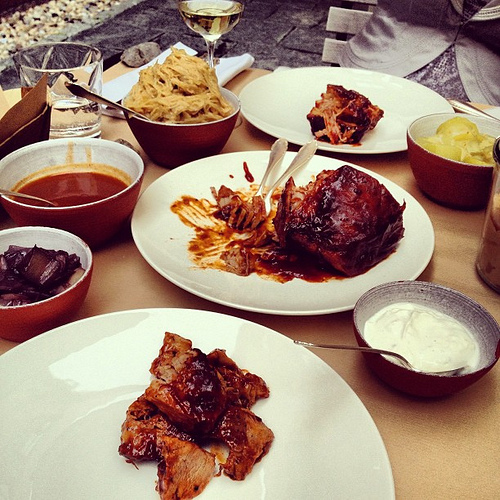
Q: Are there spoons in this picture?
A: Yes, there is a spoon.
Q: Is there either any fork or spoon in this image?
A: Yes, there is a spoon.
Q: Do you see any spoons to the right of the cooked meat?
A: Yes, there is a spoon to the right of the meat.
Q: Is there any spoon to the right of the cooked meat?
A: Yes, there is a spoon to the right of the meat.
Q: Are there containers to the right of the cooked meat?
A: No, there is a spoon to the right of the meat.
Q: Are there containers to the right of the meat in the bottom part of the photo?
A: No, there is a spoon to the right of the meat.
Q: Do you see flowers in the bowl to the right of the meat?
A: No, there is a spoon in the bowl.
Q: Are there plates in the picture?
A: Yes, there is a plate.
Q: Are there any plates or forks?
A: Yes, there is a plate.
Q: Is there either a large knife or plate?
A: Yes, there is a large plate.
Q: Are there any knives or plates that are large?
A: Yes, the plate is large.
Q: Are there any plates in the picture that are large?
A: Yes, there is a large plate.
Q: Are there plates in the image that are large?
A: Yes, there is a plate that is large.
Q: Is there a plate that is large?
A: Yes, there is a plate that is large.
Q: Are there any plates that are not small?
A: Yes, there is a large plate.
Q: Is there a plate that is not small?
A: Yes, there is a large plate.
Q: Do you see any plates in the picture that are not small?
A: Yes, there is a large plate.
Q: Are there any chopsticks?
A: No, there are no chopsticks.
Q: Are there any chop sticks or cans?
A: No, there are no chop sticks or cans.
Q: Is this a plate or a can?
A: This is a plate.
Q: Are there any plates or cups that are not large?
A: No, there is a plate but it is large.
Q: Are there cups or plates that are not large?
A: No, there is a plate but it is large.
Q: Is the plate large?
A: Yes, the plate is large.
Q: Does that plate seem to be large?
A: Yes, the plate is large.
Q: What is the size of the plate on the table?
A: The plate is large.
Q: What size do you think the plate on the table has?
A: The plate has large size.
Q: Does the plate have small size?
A: No, the plate is large.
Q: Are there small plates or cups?
A: No, there is a plate but it is large.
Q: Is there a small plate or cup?
A: No, there is a plate but it is large.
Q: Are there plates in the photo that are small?
A: No, there is a plate but it is large.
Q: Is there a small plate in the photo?
A: No, there is a plate but it is large.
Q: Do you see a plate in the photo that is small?
A: No, there is a plate but it is large.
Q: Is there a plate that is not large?
A: No, there is a plate but it is large.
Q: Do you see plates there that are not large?
A: No, there is a plate but it is large.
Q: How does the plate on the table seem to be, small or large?
A: The plate is large.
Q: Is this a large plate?
A: Yes, this is a large plate.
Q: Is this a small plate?
A: No, this is a large plate.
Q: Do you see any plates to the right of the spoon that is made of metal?
A: Yes, there is a plate to the right of the spoon.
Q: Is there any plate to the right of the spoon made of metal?
A: Yes, there is a plate to the right of the spoon.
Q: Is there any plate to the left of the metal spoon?
A: No, the plate is to the right of the spoon.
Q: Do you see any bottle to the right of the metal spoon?
A: No, there is a plate to the right of the spoon.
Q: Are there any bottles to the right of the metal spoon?
A: No, there is a plate to the right of the spoon.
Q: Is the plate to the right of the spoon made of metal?
A: Yes, the plate is to the right of the spoon.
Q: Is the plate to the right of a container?
A: No, the plate is to the right of the spoon.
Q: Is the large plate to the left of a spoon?
A: No, the plate is to the right of a spoon.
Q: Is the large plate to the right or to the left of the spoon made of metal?
A: The plate is to the right of the spoon.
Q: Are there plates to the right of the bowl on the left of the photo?
A: Yes, there is a plate to the right of the bowl.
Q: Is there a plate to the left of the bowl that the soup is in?
A: No, the plate is to the right of the bowl.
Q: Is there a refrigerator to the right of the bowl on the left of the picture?
A: No, there is a plate to the right of the bowl.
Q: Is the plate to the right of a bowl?
A: Yes, the plate is to the right of a bowl.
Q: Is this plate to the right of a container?
A: No, the plate is to the right of a bowl.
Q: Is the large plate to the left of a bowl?
A: No, the plate is to the right of a bowl.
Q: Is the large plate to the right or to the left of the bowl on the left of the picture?
A: The plate is to the right of the bowl.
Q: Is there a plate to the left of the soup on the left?
A: No, the plate is to the right of the soup.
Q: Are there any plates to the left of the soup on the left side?
A: No, the plate is to the right of the soup.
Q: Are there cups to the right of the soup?
A: No, there is a plate to the right of the soup.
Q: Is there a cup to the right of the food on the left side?
A: No, there is a plate to the right of the soup.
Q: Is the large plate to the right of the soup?
A: Yes, the plate is to the right of the soup.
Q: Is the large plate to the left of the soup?
A: No, the plate is to the right of the soup.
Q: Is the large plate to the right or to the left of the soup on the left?
A: The plate is to the right of the soup.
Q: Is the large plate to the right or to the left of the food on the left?
A: The plate is to the right of the soup.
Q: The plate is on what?
A: The plate is on the table.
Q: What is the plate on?
A: The plate is on the table.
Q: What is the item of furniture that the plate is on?
A: The piece of furniture is a table.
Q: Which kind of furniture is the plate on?
A: The plate is on the table.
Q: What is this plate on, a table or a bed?
A: The plate is on a table.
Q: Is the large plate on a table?
A: Yes, the plate is on a table.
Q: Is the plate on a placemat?
A: No, the plate is on a table.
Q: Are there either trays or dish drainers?
A: No, there are no trays or dish drainers.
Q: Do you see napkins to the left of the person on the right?
A: Yes, there is a napkin to the left of the person.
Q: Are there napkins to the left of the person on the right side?
A: Yes, there is a napkin to the left of the person.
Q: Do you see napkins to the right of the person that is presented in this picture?
A: No, the napkin is to the left of the person.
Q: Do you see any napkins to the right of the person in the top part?
A: No, the napkin is to the left of the person.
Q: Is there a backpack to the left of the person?
A: No, there is a napkin to the left of the person.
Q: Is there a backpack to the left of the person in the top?
A: No, there is a napkin to the left of the person.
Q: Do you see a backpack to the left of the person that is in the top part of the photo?
A: No, there is a napkin to the left of the person.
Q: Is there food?
A: Yes, there is food.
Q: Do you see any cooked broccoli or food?
A: Yes, there is cooked food.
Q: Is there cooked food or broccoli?
A: Yes, there is cooked food.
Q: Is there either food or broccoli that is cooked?
A: Yes, the food is cooked.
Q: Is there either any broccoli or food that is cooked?
A: Yes, the food is cooked.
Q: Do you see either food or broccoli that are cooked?
A: Yes, the food is cooked.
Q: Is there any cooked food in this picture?
A: Yes, there is cooked food.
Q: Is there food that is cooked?
A: Yes, there is food that is cooked.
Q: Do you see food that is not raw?
A: Yes, there is cooked food.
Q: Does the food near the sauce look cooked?
A: Yes, the food is cooked.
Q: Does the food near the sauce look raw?
A: No, the food is cooked.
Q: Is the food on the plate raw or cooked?
A: The food is cooked.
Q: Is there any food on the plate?
A: Yes, there is food on the plate.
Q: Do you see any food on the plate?
A: Yes, there is food on the plate.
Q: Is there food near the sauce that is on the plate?
A: Yes, there is food near the sauce.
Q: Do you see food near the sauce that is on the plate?
A: Yes, there is food near the sauce.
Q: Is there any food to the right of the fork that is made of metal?
A: Yes, there is food to the right of the fork.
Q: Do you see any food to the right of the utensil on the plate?
A: Yes, there is food to the right of the fork.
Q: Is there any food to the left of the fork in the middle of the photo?
A: No, the food is to the right of the fork.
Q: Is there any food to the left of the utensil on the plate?
A: No, the food is to the right of the fork.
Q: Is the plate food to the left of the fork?
A: No, the food is to the right of the fork.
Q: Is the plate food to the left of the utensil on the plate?
A: No, the food is to the right of the fork.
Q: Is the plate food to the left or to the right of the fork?
A: The food is to the right of the fork.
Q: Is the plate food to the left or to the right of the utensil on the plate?
A: The food is to the right of the fork.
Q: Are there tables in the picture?
A: Yes, there is a table.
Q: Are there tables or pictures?
A: Yes, there is a table.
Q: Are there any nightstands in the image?
A: No, there are no nightstands.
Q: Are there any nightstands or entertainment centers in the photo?
A: No, there are no nightstands or entertainment centers.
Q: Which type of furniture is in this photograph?
A: The furniture is a table.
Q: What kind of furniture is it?
A: The piece of furniture is a table.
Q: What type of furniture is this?
A: That is a table.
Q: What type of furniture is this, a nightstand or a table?
A: That is a table.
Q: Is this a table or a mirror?
A: This is a table.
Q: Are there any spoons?
A: Yes, there is a spoon.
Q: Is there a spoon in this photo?
A: Yes, there is a spoon.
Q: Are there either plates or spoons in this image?
A: Yes, there is a spoon.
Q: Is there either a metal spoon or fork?
A: Yes, there is a metal spoon.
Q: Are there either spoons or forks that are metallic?
A: Yes, the spoon is metallic.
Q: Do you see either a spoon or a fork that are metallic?
A: Yes, the spoon is metallic.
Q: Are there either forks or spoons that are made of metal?
A: Yes, the spoon is made of metal.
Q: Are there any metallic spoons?
A: Yes, there is a metal spoon.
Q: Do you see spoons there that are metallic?
A: Yes, there is a spoon that is metallic.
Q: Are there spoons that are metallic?
A: Yes, there is a spoon that is metallic.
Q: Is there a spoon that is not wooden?
A: Yes, there is a metallic spoon.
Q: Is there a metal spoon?
A: Yes, there is a spoon that is made of metal.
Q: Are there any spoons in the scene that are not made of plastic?
A: Yes, there is a spoon that is made of metal.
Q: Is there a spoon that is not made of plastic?
A: Yes, there is a spoon that is made of metal.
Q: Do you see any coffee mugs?
A: No, there are no coffee mugs.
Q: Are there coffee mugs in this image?
A: No, there are no coffee mugs.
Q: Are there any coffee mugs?
A: No, there are no coffee mugs.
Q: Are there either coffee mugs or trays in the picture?
A: No, there are no coffee mugs or trays.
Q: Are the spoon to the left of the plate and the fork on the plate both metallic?
A: Yes, both the spoon and the fork are metallic.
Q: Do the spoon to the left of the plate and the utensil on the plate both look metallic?
A: Yes, both the spoon and the fork are metallic.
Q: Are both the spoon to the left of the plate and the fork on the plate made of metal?
A: Yes, both the spoon and the fork are made of metal.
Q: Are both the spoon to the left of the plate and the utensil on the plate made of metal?
A: Yes, both the spoon and the fork are made of metal.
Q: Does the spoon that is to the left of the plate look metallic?
A: Yes, the spoon is metallic.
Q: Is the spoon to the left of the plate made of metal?
A: Yes, the spoon is made of metal.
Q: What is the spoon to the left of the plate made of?
A: The spoon is made of metal.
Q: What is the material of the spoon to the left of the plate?
A: The spoon is made of metal.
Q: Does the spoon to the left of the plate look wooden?
A: No, the spoon is metallic.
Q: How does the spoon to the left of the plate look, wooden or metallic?
A: The spoon is metallic.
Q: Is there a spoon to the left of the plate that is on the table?
A: Yes, there is a spoon to the left of the plate.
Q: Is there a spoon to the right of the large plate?
A: No, the spoon is to the left of the plate.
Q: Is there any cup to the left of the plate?
A: No, there is a spoon to the left of the plate.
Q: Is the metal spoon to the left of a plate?
A: Yes, the spoon is to the left of a plate.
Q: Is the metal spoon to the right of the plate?
A: No, the spoon is to the left of the plate.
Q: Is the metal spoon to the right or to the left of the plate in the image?
A: The spoon is to the left of the plate.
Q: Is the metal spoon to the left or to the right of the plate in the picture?
A: The spoon is to the left of the plate.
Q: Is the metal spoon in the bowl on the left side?
A: Yes, the spoon is in the bowl.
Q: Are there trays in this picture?
A: No, there are no trays.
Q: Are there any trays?
A: No, there are no trays.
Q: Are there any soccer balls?
A: No, there are no soccer balls.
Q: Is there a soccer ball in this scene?
A: No, there are no soccer balls.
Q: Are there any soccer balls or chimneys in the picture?
A: No, there are no soccer balls or chimneys.